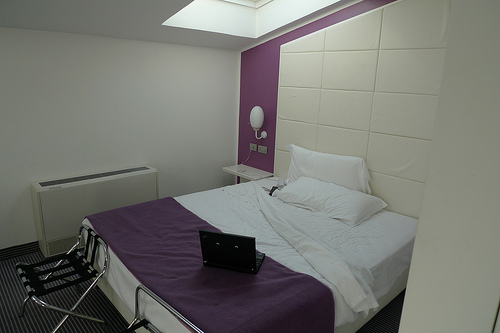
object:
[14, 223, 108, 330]
chair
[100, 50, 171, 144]
wall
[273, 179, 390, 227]
pillow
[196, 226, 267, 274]
computer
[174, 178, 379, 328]
blanket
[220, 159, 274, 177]
table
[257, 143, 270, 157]
electrical plate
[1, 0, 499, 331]
bedroom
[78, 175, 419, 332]
bed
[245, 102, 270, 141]
lamp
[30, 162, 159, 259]
heater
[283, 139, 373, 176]
pillow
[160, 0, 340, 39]
skylight window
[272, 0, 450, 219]
wall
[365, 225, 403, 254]
sheet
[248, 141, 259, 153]
electrical outlet